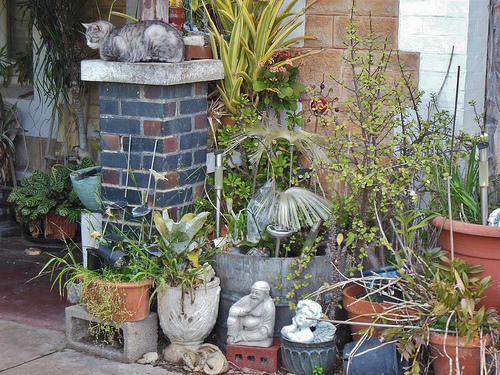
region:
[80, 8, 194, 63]
grey cat on a pillar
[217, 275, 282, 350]
small concrete garden statue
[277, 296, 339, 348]
small concrete garden statue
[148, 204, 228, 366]
vase with plant inside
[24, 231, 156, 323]
vase with plant inside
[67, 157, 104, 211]
blue ceramic flower pot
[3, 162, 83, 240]
vase with plant inside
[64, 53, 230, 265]
pillar made from brick and cement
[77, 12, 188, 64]
grey cat sitting down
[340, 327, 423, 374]
flower pot on its side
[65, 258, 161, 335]
Plant on a cement stone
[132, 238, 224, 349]
Plant in a pot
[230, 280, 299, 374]
Budda on a brick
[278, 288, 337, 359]
Stone statue in a pot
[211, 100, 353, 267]
Plants in a pot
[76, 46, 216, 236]
Stone structure by a wall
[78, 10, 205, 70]
Cat on a post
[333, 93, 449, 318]
Tree in a pot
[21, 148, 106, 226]
Plant in a pot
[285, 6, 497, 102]
Brick wall on a building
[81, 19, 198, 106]
gray and white tabby cat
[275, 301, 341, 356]
small stone angel statue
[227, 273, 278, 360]
small stone buddah statue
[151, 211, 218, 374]
stone urn with plants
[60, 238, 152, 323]
clay pot with plants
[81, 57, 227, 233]
brick pillar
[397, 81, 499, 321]
large flowerpot with plants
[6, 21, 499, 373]
unmaintained garden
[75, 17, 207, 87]
kitty cat sitting on pillar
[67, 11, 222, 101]
gray and white cat watching door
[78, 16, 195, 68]
cat sitting on brick pedestal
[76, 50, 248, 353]
red and black brick pedestal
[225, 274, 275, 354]
white plaster statue on top of a brick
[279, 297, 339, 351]
white plaster angel statue in a bucket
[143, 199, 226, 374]
green plant in white planter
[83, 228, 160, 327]
plant in tan flower pot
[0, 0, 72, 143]
window with thick white frame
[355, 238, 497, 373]
plant in orangish red pot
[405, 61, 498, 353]
plant in large orangish red pot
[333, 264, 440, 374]
empty flower pots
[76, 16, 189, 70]
a grey and white cat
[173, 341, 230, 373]
a resting dragon statue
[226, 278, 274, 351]
a white statue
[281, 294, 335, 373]
an angel statue in a pot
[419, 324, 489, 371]
a red clay pot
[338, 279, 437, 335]
a red clay pot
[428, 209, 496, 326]
a red clay pot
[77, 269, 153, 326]
a red clay pot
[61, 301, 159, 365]
a grey brick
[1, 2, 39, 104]
a building window